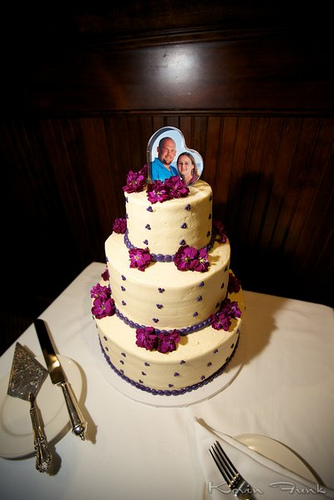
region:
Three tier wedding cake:
[86, 167, 253, 396]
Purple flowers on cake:
[86, 285, 115, 319]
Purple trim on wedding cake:
[110, 363, 187, 399]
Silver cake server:
[5, 339, 58, 473]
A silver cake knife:
[33, 311, 90, 445]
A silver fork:
[201, 435, 250, 496]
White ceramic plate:
[1, 353, 86, 457]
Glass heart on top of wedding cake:
[137, 120, 207, 178]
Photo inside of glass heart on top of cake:
[142, 118, 193, 172]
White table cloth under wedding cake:
[258, 313, 322, 415]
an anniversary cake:
[86, 110, 255, 402]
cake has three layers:
[81, 120, 258, 408]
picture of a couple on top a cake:
[83, 114, 254, 396]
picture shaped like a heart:
[141, 122, 207, 186]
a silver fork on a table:
[205, 439, 257, 498]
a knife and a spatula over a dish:
[0, 313, 91, 477]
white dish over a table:
[0, 348, 87, 467]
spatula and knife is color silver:
[6, 311, 94, 475]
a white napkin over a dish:
[183, 414, 329, 497]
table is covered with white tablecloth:
[3, 252, 332, 498]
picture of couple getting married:
[145, 123, 205, 189]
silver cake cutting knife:
[33, 319, 88, 431]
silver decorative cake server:
[7, 343, 50, 477]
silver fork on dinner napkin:
[206, 439, 255, 497]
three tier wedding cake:
[89, 181, 247, 394]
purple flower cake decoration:
[132, 325, 154, 347]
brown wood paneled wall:
[2, 61, 330, 209]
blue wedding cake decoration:
[154, 283, 165, 293]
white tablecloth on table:
[0, 262, 330, 496]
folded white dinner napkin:
[194, 420, 331, 499]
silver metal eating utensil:
[0, 337, 63, 475]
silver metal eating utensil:
[31, 316, 95, 447]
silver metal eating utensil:
[203, 438, 253, 499]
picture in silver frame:
[137, 121, 212, 197]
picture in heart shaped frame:
[135, 118, 211, 196]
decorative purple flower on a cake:
[170, 243, 198, 273]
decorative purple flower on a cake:
[154, 326, 181, 357]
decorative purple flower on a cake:
[130, 323, 157, 351]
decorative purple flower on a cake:
[88, 294, 114, 317]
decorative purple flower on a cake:
[126, 244, 156, 270]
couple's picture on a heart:
[151, 123, 212, 200]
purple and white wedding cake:
[98, 162, 254, 406]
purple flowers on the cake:
[119, 313, 205, 373]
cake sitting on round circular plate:
[92, 324, 269, 442]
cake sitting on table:
[54, 314, 331, 445]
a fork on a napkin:
[192, 438, 276, 497]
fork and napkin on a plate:
[184, 413, 305, 496]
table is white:
[106, 383, 189, 493]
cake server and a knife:
[0, 325, 94, 470]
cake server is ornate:
[3, 341, 73, 487]